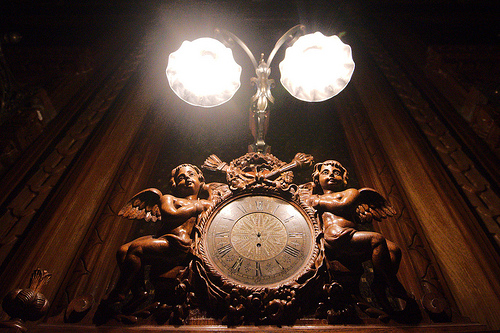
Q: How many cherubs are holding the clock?
A: Two.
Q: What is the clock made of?
A: Wood.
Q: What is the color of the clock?
A: Brown.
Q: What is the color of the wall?
A: Brown.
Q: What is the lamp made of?
A: Metal.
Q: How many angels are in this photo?
A: Two.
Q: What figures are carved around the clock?
A: Angels.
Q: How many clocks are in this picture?
A: One.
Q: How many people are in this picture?
A: Zero.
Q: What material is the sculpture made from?
A: Wood.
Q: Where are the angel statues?
A: Around the clock.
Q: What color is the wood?
A: Brown.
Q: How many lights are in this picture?
A: Two.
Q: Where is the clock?
A: On the wall.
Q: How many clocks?
A: 1.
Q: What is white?
A: Lights.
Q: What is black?
A: Hands on the clock.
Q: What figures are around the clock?
A: Cherubs.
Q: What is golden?
A: Face of a clock.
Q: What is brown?
A: Wall.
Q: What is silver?
A: Light fixtures.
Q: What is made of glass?
A: Light bulbs.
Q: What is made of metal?
A: The arm holding the light.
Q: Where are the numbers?
A: On the clock.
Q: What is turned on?
A: Lamps.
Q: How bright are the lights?
A: Very bright.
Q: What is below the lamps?
A: Clock.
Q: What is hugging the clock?
A: Angels.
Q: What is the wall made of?
A: Wood.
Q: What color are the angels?
A: Gold.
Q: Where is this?
A: Coliseum.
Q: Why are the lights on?
A: It is night time.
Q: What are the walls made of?
A: Wood.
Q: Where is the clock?
A: On the wall.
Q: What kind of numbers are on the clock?
A: Roman.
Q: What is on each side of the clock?
A: A cherub.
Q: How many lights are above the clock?
A: Two.